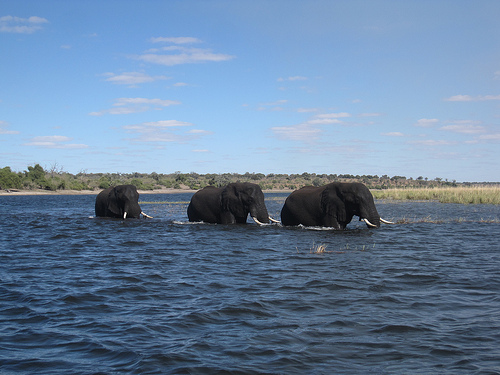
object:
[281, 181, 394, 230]
elephant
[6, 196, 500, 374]
water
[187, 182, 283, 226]
elephant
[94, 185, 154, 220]
elephant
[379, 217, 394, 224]
tusk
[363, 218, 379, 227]
tusk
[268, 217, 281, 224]
tusk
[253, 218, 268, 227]
tusk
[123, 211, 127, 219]
tusks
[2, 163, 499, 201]
vegetation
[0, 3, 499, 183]
sky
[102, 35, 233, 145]
clouds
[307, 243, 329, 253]
grass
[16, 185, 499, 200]
shore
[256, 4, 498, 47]
cloudless